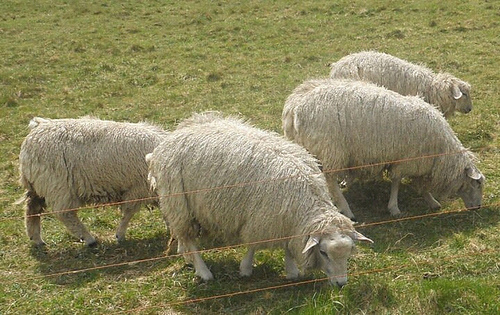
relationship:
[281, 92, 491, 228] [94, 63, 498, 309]
sheep eating eating grass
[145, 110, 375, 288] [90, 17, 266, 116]
sheep on field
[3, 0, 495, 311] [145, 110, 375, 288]
field under sheep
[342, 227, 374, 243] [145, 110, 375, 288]
ear of sheep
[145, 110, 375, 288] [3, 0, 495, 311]
sheep in field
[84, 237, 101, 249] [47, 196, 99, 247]
hoove on leg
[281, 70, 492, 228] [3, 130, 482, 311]
sheep grazing behind fence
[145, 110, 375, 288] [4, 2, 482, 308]
sheep eating grass